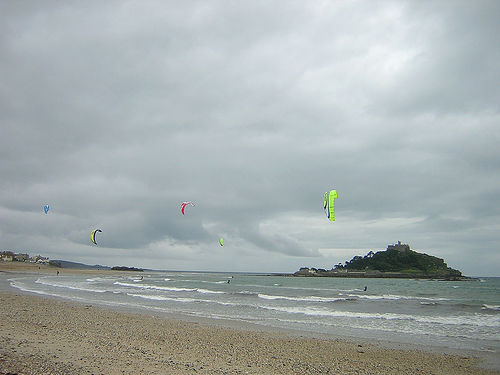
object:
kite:
[317, 187, 346, 224]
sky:
[2, 1, 498, 280]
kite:
[177, 196, 193, 218]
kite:
[215, 234, 236, 253]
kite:
[86, 225, 105, 246]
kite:
[42, 203, 52, 214]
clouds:
[0, 3, 491, 276]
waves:
[14, 270, 494, 355]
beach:
[1, 275, 499, 374]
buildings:
[1, 248, 52, 266]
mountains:
[297, 239, 468, 280]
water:
[12, 272, 498, 352]